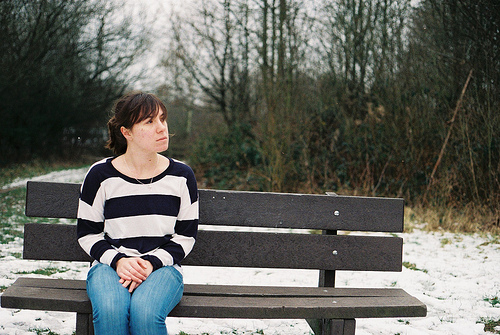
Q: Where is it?
A: This is at the field.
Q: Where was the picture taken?
A: It was taken at the field.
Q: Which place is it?
A: It is a field.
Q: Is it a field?
A: Yes, it is a field.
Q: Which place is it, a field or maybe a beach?
A: It is a field.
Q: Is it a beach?
A: No, it is a field.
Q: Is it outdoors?
A: Yes, it is outdoors.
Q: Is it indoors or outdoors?
A: It is outdoors.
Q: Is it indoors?
A: No, it is outdoors.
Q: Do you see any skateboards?
A: No, there are no skateboards.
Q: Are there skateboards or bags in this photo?
A: No, there are no skateboards or bags.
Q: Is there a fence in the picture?
A: No, there are no fences.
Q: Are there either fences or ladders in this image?
A: No, there are no fences or ladders.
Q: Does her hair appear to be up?
A: Yes, the hair is up.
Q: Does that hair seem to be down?
A: No, the hair is up.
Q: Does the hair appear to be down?
A: No, the hair is up.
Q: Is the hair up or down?
A: The hair is up.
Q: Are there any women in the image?
A: Yes, there is a woman.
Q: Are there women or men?
A: Yes, there is a woman.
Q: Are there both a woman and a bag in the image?
A: No, there is a woman but no bags.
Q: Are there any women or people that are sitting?
A: Yes, the woman is sitting.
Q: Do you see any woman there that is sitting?
A: Yes, there is a woman that is sitting.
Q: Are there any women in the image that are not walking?
A: Yes, there is a woman that is sitting.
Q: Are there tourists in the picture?
A: No, there are no tourists.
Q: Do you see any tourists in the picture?
A: No, there are no tourists.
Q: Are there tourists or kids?
A: No, there are no tourists or kids.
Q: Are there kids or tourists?
A: No, there are no tourists or kids.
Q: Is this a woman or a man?
A: This is a woman.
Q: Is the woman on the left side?
A: Yes, the woman is on the left of the image.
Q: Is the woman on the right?
A: No, the woman is on the left of the image.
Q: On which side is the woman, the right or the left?
A: The woman is on the left of the image.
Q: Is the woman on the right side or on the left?
A: The woman is on the left of the image.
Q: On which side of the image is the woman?
A: The woman is on the left of the image.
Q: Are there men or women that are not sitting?
A: No, there is a woman but she is sitting.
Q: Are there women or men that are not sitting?
A: No, there is a woman but she is sitting.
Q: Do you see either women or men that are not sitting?
A: No, there is a woman but she is sitting.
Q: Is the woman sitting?
A: Yes, the woman is sitting.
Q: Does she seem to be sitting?
A: Yes, the woman is sitting.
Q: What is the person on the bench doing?
A: The woman is sitting.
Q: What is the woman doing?
A: The woman is sitting.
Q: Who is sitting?
A: The woman is sitting.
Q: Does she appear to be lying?
A: No, the woman is sitting.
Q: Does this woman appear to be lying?
A: No, the woman is sitting.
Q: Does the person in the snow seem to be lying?
A: No, the woman is sitting.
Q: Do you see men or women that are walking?
A: No, there is a woman but she is sitting.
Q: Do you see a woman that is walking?
A: No, there is a woman but she is sitting.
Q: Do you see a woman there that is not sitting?
A: No, there is a woman but she is sitting.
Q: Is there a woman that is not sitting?
A: No, there is a woman but she is sitting.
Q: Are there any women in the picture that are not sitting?
A: No, there is a woman but she is sitting.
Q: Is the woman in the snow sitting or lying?
A: The woman is sitting.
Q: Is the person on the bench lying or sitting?
A: The woman is sitting.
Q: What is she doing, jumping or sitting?
A: The woman is sitting.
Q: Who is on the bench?
A: The woman is on the bench.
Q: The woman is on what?
A: The woman is on the bench.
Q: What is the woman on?
A: The woman is on the bench.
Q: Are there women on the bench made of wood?
A: Yes, there is a woman on the bench.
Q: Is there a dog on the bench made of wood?
A: No, there is a woman on the bench.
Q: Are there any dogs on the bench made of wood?
A: No, there is a woman on the bench.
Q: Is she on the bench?
A: Yes, the woman is on the bench.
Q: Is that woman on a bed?
A: No, the woman is on the bench.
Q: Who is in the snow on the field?
A: The woman is in the snow.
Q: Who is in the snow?
A: The woman is in the snow.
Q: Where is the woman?
A: The woman is in the snow.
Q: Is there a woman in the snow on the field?
A: Yes, there is a woman in the snow.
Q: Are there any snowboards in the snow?
A: No, there is a woman in the snow.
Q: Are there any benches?
A: Yes, there is a bench.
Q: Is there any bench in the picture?
A: Yes, there is a bench.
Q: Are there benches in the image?
A: Yes, there is a bench.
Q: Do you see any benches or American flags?
A: Yes, there is a bench.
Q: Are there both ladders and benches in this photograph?
A: No, there is a bench but no ladders.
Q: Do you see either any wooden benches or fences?
A: Yes, there is a wood bench.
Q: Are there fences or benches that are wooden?
A: Yes, the bench is wooden.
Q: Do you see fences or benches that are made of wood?
A: Yes, the bench is made of wood.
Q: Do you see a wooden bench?
A: Yes, there is a wood bench.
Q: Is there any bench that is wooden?
A: Yes, there is a bench that is wooden.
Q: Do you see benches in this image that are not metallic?
A: Yes, there is a wooden bench.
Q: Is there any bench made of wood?
A: Yes, there is a bench that is made of wood.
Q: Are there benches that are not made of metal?
A: Yes, there is a bench that is made of wood.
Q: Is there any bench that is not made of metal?
A: Yes, there is a bench that is made of wood.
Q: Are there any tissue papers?
A: No, there are no tissue papers.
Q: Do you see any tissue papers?
A: No, there are no tissue papers.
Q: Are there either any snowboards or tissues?
A: No, there are no tissues or snowboards.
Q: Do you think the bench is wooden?
A: Yes, the bench is wooden.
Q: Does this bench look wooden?
A: Yes, the bench is wooden.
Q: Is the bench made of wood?
A: Yes, the bench is made of wood.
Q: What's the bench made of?
A: The bench is made of wood.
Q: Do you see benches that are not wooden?
A: No, there is a bench but it is wooden.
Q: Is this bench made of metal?
A: No, the bench is made of wood.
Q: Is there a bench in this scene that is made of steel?
A: No, there is a bench but it is made of wood.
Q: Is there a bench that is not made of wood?
A: No, there is a bench but it is made of wood.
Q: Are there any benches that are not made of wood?
A: No, there is a bench but it is made of wood.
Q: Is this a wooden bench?
A: Yes, this is a wooden bench.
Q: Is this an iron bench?
A: No, this is a wooden bench.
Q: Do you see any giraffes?
A: No, there are no giraffes.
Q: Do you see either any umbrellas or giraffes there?
A: No, there are no giraffes or umbrellas.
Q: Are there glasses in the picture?
A: No, there are no glasses.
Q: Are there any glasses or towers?
A: No, there are no glasses or towers.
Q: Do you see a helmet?
A: No, there are no helmets.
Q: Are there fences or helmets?
A: No, there are no helmets or fences.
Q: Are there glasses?
A: No, there are no glasses.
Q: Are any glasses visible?
A: No, there are no glasses.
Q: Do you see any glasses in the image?
A: No, there are no glasses.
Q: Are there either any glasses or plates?
A: No, there are no glasses or plates.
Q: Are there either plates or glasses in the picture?
A: No, there are no glasses or plates.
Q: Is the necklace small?
A: Yes, the necklace is small.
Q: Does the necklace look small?
A: Yes, the necklace is small.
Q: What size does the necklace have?
A: The necklace has small size.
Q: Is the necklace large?
A: No, the necklace is small.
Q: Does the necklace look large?
A: No, the necklace is small.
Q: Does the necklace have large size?
A: No, the necklace is small.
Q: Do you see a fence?
A: No, there are no fences.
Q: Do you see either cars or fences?
A: No, there are no fences or cars.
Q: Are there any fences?
A: No, there are no fences.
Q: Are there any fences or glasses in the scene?
A: No, there are no fences or glasses.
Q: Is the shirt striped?
A: Yes, the shirt is striped.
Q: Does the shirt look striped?
A: Yes, the shirt is striped.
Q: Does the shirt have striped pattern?
A: Yes, the shirt is striped.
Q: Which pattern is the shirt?
A: The shirt is striped.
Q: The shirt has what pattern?
A: The shirt is striped.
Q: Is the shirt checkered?
A: No, the shirt is striped.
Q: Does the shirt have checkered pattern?
A: No, the shirt is striped.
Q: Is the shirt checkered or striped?
A: The shirt is striped.